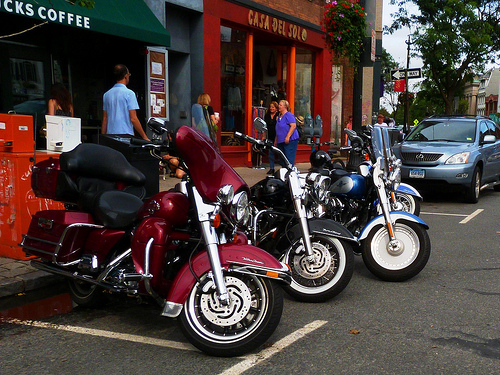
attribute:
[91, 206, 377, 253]
motorcycles — parked, sitting, maroon, black\, burgundy, black, blue, cranberry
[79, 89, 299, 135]
people — walking, patronizing, city, daytime, lunch, break, enjoying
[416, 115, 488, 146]
car — blue, parked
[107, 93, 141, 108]
shirt — blue, purple, black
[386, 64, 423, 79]
sign — pointing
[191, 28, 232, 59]
building — red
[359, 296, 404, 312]
ground — asphalt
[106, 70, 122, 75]
hair — black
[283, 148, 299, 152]
pants — blue